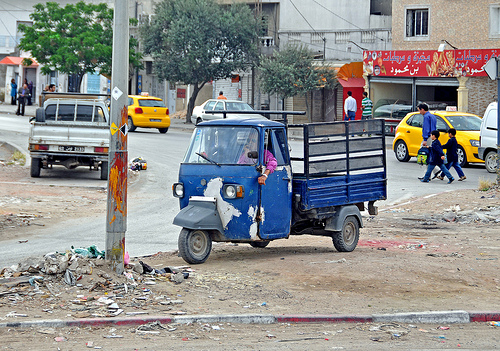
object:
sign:
[360, 51, 498, 78]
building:
[358, 0, 500, 143]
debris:
[0, 242, 203, 349]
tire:
[34, 106, 48, 124]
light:
[223, 184, 238, 199]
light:
[172, 182, 185, 198]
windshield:
[179, 123, 263, 166]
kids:
[418, 129, 456, 185]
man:
[415, 103, 444, 181]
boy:
[435, 127, 467, 182]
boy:
[418, 130, 457, 185]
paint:
[194, 176, 268, 242]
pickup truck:
[29, 91, 110, 181]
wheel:
[330, 211, 361, 254]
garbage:
[129, 155, 149, 171]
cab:
[127, 92, 173, 134]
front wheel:
[176, 221, 212, 266]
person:
[233, 130, 279, 186]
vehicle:
[173, 107, 390, 266]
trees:
[252, 44, 341, 123]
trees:
[138, 0, 266, 125]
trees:
[15, 1, 139, 104]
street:
[1, 111, 500, 268]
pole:
[107, 0, 129, 259]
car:
[390, 108, 487, 166]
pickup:
[170, 109, 392, 267]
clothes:
[237, 148, 279, 174]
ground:
[0, 132, 500, 351]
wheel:
[176, 225, 211, 264]